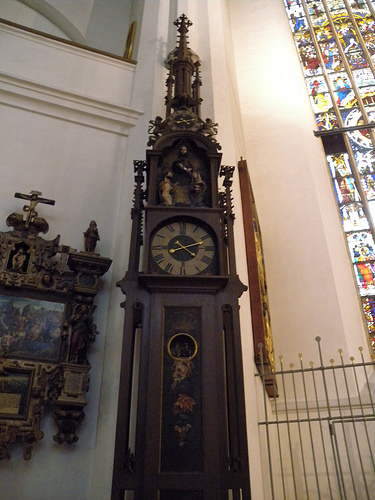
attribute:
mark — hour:
[177, 240, 215, 254]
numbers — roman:
[140, 243, 210, 274]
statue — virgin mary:
[65, 205, 112, 256]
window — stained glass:
[306, 40, 373, 150]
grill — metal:
[245, 363, 373, 467]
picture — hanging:
[0, 276, 94, 376]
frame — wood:
[0, 202, 108, 306]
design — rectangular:
[154, 300, 231, 469]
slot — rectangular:
[121, 292, 141, 465]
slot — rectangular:
[218, 302, 241, 471]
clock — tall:
[151, 213, 212, 272]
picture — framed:
[236, 156, 287, 404]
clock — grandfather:
[144, 214, 219, 271]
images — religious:
[131, 100, 225, 145]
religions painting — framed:
[3, 185, 103, 461]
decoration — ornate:
[254, 333, 373, 499]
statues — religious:
[158, 156, 207, 202]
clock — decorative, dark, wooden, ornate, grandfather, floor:
[109, 11, 252, 498]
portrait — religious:
[3, 291, 59, 358]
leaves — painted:
[173, 394, 196, 411]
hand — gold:
[173, 242, 198, 253]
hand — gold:
[177, 242, 194, 255]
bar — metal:
[249, 329, 374, 491]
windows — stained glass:
[282, 1, 374, 358]